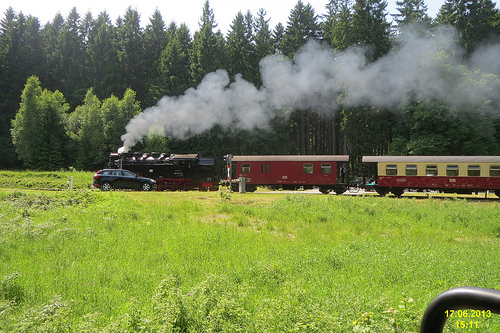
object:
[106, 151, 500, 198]
train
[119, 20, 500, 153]
smoke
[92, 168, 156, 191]
car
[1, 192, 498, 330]
grass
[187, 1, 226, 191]
tree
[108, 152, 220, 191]
engine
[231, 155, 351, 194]
passenger car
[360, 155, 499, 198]
passenger car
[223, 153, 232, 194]
railroad signal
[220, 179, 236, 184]
arm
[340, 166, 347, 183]
conductor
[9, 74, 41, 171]
bush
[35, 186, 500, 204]
road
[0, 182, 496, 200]
track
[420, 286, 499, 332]
pole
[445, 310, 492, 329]
time stamp